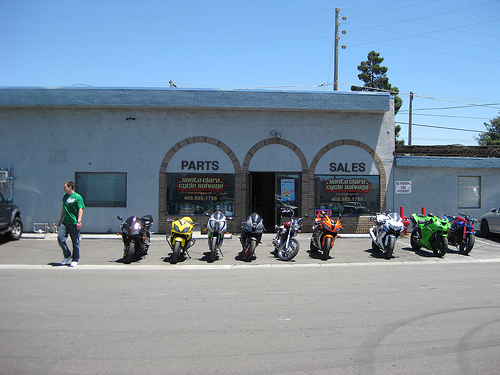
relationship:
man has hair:
[57, 181, 86, 267] [65, 178, 78, 192]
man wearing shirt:
[53, 178, 90, 268] [51, 190, 86, 228]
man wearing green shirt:
[53, 178, 90, 268] [61, 192, 86, 225]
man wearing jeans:
[57, 181, 86, 267] [57, 222, 81, 262]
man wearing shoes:
[57, 181, 86, 267] [59, 257, 81, 265]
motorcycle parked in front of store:
[115, 214, 154, 264] [0, 87, 395, 231]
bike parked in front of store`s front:
[166, 216, 198, 262] [1, 231, 498, 373]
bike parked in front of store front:
[310, 210, 344, 259] [0, 78, 398, 241]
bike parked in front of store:
[409, 211, 451, 256] [0, 87, 395, 231]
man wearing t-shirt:
[57, 181, 86, 267] [56, 187, 87, 227]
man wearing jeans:
[57, 181, 86, 267] [51, 217, 81, 263]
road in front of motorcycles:
[10, 273, 458, 356] [111, 209, 471, 267]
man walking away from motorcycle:
[57, 181, 86, 267] [111, 218, 163, 268]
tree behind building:
[352, 49, 406, 150] [0, 68, 410, 263]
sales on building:
[329, 162, 365, 172] [0, 86, 499, 232]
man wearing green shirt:
[57, 181, 86, 267] [61, 192, 86, 225]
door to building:
[255, 149, 307, 227] [0, 85, 397, 235]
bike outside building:
[166, 216, 198, 262] [0, 85, 397, 235]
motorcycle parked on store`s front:
[369, 200, 411, 265] [1, 231, 500, 373]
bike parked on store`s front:
[310, 210, 344, 259] [1, 231, 500, 373]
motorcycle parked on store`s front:
[238, 210, 265, 262] [1, 231, 500, 373]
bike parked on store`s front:
[166, 216, 198, 262] [1, 231, 500, 373]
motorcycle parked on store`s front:
[115, 214, 154, 264] [1, 231, 500, 373]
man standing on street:
[57, 181, 86, 267] [1, 235, 497, 374]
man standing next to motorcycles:
[57, 181, 86, 267] [107, 182, 481, 264]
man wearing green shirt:
[57, 181, 86, 267] [39, 161, 165, 327]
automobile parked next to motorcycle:
[482, 201, 498, 242] [441, 213, 481, 255]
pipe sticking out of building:
[27, 217, 55, 235] [0, 86, 396, 234]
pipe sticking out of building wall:
[27, 217, 55, 235] [385, 157, 497, 234]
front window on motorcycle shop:
[162, 174, 242, 222] [0, 73, 498, 223]